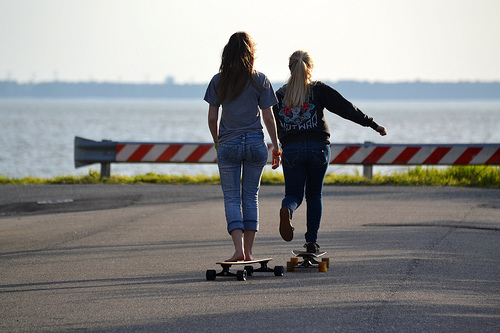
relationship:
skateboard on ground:
[199, 247, 287, 285] [0, 181, 499, 333]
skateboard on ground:
[280, 245, 337, 275] [0, 181, 499, 333]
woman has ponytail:
[272, 48, 390, 277] [282, 49, 317, 113]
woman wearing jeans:
[200, 26, 289, 288] [209, 128, 270, 239]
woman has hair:
[200, 26, 289, 288] [212, 30, 259, 109]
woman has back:
[200, 26, 289, 288] [212, 73, 264, 127]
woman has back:
[272, 48, 390, 277] [279, 85, 326, 134]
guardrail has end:
[69, 128, 500, 194] [66, 130, 96, 172]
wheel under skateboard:
[201, 266, 220, 284] [199, 247, 287, 285]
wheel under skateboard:
[232, 267, 251, 284] [199, 247, 287, 285]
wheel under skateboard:
[269, 261, 288, 280] [199, 247, 287, 285]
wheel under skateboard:
[239, 264, 257, 277] [199, 247, 287, 285]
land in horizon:
[10, 74, 500, 103] [0, 1, 498, 96]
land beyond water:
[10, 74, 500, 103] [3, 96, 500, 179]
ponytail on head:
[282, 49, 317, 113] [281, 48, 321, 84]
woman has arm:
[272, 48, 390, 277] [321, 82, 390, 145]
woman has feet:
[200, 26, 289, 288] [218, 243, 259, 263]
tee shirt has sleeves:
[194, 68, 282, 150] [198, 76, 280, 111]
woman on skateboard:
[200, 26, 289, 288] [199, 247, 287, 285]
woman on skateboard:
[272, 48, 390, 277] [280, 245, 337, 275]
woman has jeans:
[200, 26, 289, 288] [209, 128, 270, 239]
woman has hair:
[272, 48, 390, 277] [278, 46, 320, 120]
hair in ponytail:
[278, 46, 320, 120] [282, 49, 317, 113]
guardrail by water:
[69, 128, 500, 194] [3, 96, 500, 179]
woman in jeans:
[200, 26, 289, 288] [209, 128, 270, 239]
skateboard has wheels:
[280, 245, 337, 275] [282, 253, 334, 279]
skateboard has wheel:
[280, 245, 337, 275] [283, 258, 300, 276]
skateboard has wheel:
[280, 245, 337, 275] [315, 259, 333, 278]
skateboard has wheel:
[280, 245, 337, 275] [318, 256, 334, 270]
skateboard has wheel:
[280, 245, 337, 275] [285, 254, 304, 268]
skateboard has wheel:
[199, 247, 287, 285] [201, 266, 220, 284]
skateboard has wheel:
[199, 247, 287, 285] [232, 267, 251, 284]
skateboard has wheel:
[280, 245, 337, 275] [269, 261, 288, 280]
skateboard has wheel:
[199, 247, 287, 285] [239, 264, 257, 277]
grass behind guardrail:
[2, 164, 499, 193] [69, 128, 500, 194]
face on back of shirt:
[279, 95, 313, 119] [272, 78, 380, 151]